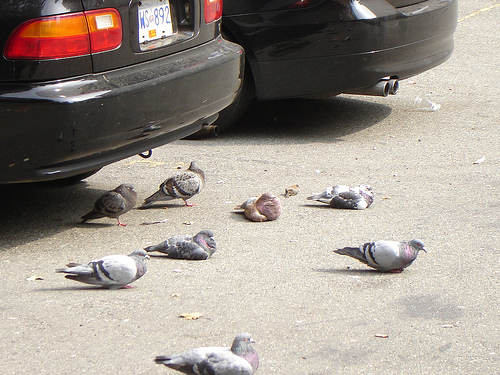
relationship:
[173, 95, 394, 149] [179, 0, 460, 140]
shadow under car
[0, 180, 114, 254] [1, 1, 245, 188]
shadow under car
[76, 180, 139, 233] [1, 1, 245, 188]
pigeon under car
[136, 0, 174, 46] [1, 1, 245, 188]
licence plate of car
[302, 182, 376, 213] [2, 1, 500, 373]
pigeon on road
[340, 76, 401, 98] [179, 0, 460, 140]
twin mufflers on car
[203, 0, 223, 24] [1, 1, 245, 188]
light on car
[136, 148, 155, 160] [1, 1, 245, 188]
tow hitch on car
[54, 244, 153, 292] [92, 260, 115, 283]
pigeon has stripes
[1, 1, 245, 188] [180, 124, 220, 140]
car has exhaust pipe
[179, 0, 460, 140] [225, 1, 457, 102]
car has bumper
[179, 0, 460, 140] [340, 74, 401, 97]
car has dual exhaust pipes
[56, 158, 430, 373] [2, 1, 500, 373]
birds on road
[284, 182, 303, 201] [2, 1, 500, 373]
leaf on road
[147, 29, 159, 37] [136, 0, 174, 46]
sticker on licence plate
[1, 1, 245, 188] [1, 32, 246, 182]
car has bumper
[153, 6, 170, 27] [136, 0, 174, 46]
892 on licence plate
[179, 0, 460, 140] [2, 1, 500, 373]
car on road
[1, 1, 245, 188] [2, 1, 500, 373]
car on road